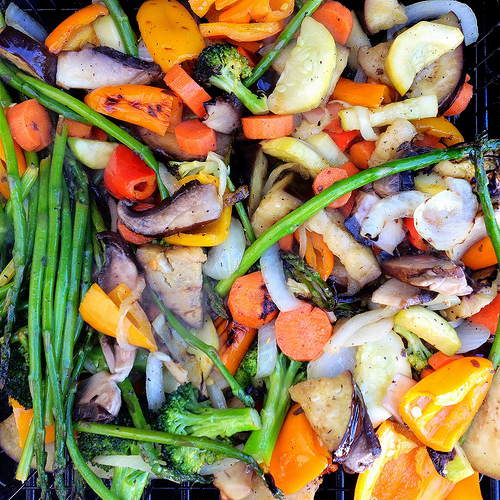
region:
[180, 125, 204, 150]
edge of a carrot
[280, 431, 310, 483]
part of a fruit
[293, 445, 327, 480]
edgfe of a fruit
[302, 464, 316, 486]
part of a fruit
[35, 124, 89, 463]
the bunch of long green vegetables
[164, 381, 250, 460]
piece of broccoli at the bottom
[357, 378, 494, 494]
yellow bellpeppers in the corner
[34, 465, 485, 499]
the metal rack that can be seen at the bottom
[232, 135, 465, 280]
the single asparagus layong by itself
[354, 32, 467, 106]
the yellow squash at the top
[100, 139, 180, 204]
the red pepper by the bunch of green vegetables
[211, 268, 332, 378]
the two carrot slices in the middle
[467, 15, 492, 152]
part of the metal rack seen on the side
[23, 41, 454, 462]
the grilled assorted vegetables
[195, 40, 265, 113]
a piece of brocolli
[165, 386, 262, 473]
a piece of brocolli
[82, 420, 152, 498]
a piece of brocolli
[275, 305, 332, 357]
a piece of carrot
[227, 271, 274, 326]
a piece of carrot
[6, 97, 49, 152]
a piece of carrot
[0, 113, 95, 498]
a bunch of aparagus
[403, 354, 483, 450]
a yellow pepper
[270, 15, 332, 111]
a piece of yellow squash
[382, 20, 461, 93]
a piece of yellow squash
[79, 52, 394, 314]
food in the photo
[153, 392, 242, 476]
green piece of food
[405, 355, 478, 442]
yellow piece of food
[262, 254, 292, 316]
white piece of food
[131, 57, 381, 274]
many different items of food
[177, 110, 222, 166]
orange piece of food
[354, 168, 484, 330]
food on the right hand side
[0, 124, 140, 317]
food on the left hand side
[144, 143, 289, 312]
middle of the food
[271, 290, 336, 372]
round carrot in the mix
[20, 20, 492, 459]
Stir fry with vegetables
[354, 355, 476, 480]
Yellow pepers in the stir fry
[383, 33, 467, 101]
There are lemons in the stir fry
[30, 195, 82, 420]
Green beans in the food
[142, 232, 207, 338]
There is meat in the stir fry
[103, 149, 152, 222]
The peppers are black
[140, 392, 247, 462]
The broccoli is green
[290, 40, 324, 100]
The lemons are yellow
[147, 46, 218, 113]
The carrots are orange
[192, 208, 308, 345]
The onion is white